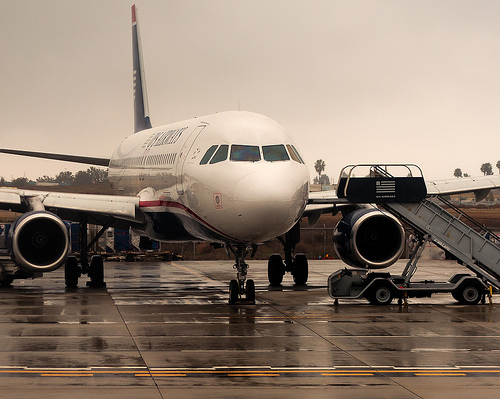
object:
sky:
[1, 25, 93, 87]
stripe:
[139, 200, 242, 242]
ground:
[1, 274, 498, 396]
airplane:
[0, 4, 500, 302]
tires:
[63, 254, 105, 293]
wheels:
[327, 267, 486, 305]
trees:
[0, 166, 109, 186]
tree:
[450, 163, 495, 199]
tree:
[315, 158, 326, 185]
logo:
[375, 179, 395, 199]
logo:
[141, 127, 188, 148]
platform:
[105, 257, 266, 395]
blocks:
[229, 279, 255, 305]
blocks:
[86, 281, 107, 289]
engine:
[9, 210, 71, 274]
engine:
[332, 206, 409, 267]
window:
[229, 144, 261, 162]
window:
[262, 144, 290, 161]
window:
[200, 145, 218, 165]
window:
[209, 144, 228, 164]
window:
[286, 144, 302, 163]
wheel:
[268, 254, 309, 285]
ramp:
[370, 163, 500, 290]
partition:
[342, 171, 428, 201]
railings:
[339, 162, 429, 182]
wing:
[0, 177, 143, 226]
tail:
[131, 3, 152, 134]